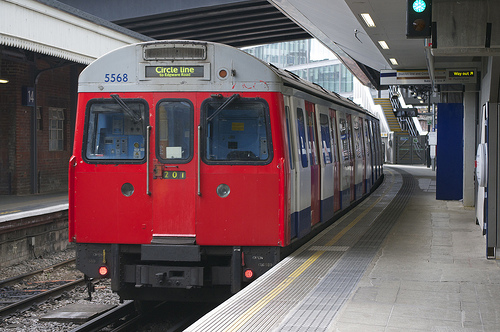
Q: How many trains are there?
A: One.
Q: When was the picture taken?
A: Daytime.